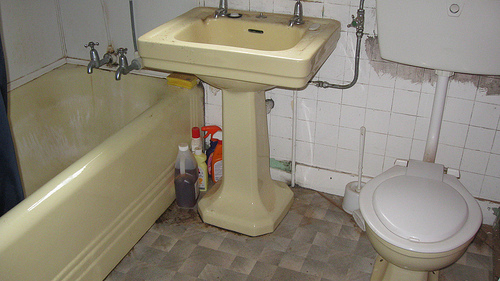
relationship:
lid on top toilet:
[377, 175, 468, 240] [358, 155, 484, 279]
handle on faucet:
[79, 37, 101, 49] [86, 48, 138, 81]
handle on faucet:
[113, 44, 128, 56] [86, 48, 138, 81]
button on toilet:
[441, 3, 468, 21] [338, 134, 497, 278]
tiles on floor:
[280, 221, 310, 264] [95, 167, 493, 279]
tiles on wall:
[281, 91, 406, 185] [157, 23, 486, 230]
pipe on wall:
[422, 69, 457, 161] [197, 2, 496, 226]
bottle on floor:
[172, 142, 198, 207] [95, 167, 493, 279]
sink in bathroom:
[135, 3, 342, 237] [8, 3, 491, 280]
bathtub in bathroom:
[1, 18, 256, 243] [8, 3, 491, 280]